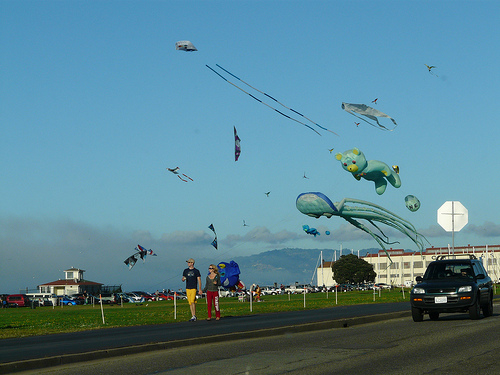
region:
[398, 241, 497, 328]
black suv driving down street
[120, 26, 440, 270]
kites flying in sky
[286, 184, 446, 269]
octopus kite flying in the sky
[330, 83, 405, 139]
fish kite flying in the sky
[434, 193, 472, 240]
white octagon traffic sign on pole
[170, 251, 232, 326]
two people walking down the street next to road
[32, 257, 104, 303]
house in green field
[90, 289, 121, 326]
white rod fence support pole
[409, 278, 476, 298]
headlights on front of suv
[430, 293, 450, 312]
white license plate on front of suv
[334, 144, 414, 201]
large kite in sky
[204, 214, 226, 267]
large kite in sky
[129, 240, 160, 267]
large kite in sky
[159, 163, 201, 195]
large kite in sky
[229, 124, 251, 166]
large kite in sky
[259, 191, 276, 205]
large kite in sky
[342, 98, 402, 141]
large kite in sky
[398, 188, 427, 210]
large kite in sky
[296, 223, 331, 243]
large kite in sky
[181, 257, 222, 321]
couple walking down the sidewalk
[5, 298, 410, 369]
a sidewalk beside the road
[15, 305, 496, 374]
the road next to the sidewalk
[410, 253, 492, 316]
black SUV in the road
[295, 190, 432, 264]
giant octopus kite in the air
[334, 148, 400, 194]
giant green teddy bear kite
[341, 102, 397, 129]
large fish kite above the bear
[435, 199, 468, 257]
back of a stop sign behind the SUV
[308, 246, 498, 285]
large white building on the right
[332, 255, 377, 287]
large tree beside the big white building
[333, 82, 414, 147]
Large kite in the blue sky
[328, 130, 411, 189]
Large kite in the blue sky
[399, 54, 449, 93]
Large kite in the blue sky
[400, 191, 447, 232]
Large kite in the blue sky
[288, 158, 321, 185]
Large kite in the blue sky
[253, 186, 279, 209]
Large kite in the blue sky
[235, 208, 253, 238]
Large kite in the blue sky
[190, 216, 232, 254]
Large kite in the blue sky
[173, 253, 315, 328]
two people walking down the side of the street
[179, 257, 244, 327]
two people walking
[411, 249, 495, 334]
a car traveling down the street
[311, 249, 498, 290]
the facade of a building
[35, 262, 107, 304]
a white building with a tower on top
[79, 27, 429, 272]
several kites flying in the sky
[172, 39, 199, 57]
a kite flying in the sky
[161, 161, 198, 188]
a kite flying in the sky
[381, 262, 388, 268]
A window on a building.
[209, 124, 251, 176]
large kite in air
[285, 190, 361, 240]
large kite in air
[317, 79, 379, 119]
large kite in air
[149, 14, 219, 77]
large kite in air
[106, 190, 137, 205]
white clouds in blue sky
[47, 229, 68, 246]
white clouds in blue sky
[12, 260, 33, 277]
white clouds in blue sky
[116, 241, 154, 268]
A kite in the sky.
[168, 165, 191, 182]
A kite in the sky.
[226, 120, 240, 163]
A kite in the sky.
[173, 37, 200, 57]
A kite in the sky.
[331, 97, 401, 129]
A kite in the sky.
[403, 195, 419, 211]
A kite in the sky.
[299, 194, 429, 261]
A kite in the sky.